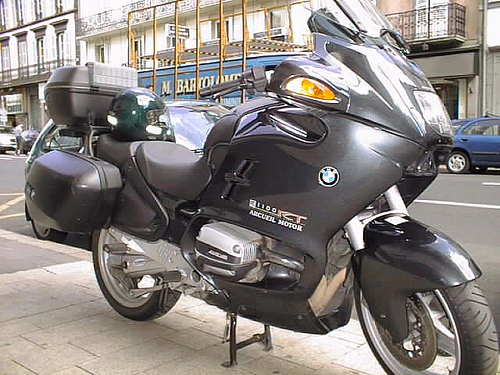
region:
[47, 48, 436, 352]
A black motorcycle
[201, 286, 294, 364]
Kickstand down on a motorcycle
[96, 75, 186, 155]
A helmet resting on the seat of a motorcycle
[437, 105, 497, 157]
A blue car on the opposite side of the road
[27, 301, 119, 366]
A brick sidewalk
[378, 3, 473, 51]
A black wrought iron balcony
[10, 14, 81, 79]
Windows in a row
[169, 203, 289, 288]
A motorcycle engine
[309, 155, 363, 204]
The BMW insignia on the side of a motorcycle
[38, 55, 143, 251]
A motorcycle's storage compartments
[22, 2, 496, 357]
Close up picture of a motorcycle.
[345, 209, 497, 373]
Front wheel of motorcycle.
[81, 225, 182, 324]
Back wheel of motorcycle.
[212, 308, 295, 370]
Kick stand on motorcycle.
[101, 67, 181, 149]
Saftey helmet sitting on motorcycle.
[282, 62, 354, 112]
Yellow light on right side.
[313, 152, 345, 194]
Vehicle emblem for motorcycle.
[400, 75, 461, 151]
Front headlight of motorcycle.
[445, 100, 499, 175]
Part of a blue vehicle.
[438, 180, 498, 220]
White traffic lines painted on street.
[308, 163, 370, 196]
the logo of the motorcycle manufacturer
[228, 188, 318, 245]
the model logo of the motorcycle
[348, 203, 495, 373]
the front wheel of the motorcycle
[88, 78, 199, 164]
a green helmet sitting on the motorcycle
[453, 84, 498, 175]
a blue car parked on the other side of the road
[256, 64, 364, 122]
the yellow blinker light of the motorcycle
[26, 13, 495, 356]
a black bmw motorcycle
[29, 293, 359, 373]
the brick sidewalk the motocycle is parked on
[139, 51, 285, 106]
the blue sign of the shop behind the motorcycle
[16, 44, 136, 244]
two luggage cases attached to the motorcycle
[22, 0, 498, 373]
Black BMW motorcycle parked on the sidewalk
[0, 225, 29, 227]
Green helmet with glass clear face mask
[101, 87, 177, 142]
Green helmet on back of bike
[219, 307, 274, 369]
Metal motorcycle stand on the bottom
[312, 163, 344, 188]
BMW logo plate on side of motorcycle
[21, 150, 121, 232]
Black compartment on side of motorcycle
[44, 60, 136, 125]
Gray top compartment on BMW motorcycle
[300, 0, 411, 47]
Black windshield wipers on motorcycle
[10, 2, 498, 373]
BMW black motorcycle parked on brick sidewalk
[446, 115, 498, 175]
Blue car near the curb on other side of street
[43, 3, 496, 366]
a motorcycle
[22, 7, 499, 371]
the motorcycle is made by BMW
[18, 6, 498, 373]
a BMW motorcycle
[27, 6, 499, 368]
the motorcycle is grey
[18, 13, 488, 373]
the motorcycle is parked on the sidewalk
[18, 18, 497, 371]
a green car is parked at the curb behind the motorcyle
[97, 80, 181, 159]
a green helmet is on the seat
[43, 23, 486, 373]
the motorcycle has two tires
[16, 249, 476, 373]
a cobblestone sidewalk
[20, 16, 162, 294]
the motorcycle has hard storage bags